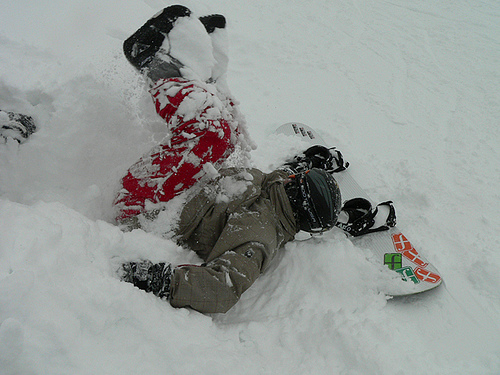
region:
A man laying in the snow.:
[88, 31, 419, 303]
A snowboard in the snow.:
[271, 126, 456, 325]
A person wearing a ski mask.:
[268, 160, 339, 238]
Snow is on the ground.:
[47, 241, 399, 371]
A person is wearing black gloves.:
[106, 245, 186, 302]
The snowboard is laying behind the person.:
[286, 128, 440, 310]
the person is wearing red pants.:
[144, 69, 235, 204]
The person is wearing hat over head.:
[300, 165, 341, 229]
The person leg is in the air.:
[118, 18, 245, 125]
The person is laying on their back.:
[71, 99, 351, 299]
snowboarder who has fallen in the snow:
[96, 0, 442, 320]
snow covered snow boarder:
[91, 4, 351, 314]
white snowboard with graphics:
[286, 113, 443, 308]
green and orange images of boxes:
[380, 230, 442, 295]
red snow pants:
[116, 68, 246, 233]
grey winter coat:
[162, 150, 297, 309]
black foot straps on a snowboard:
[298, 135, 402, 237]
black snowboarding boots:
[115, 2, 235, 64]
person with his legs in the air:
[110, 7, 340, 317]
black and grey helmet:
[288, 161, 343, 237]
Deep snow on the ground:
[2, 0, 499, 373]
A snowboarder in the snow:
[110, 3, 351, 323]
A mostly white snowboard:
[271, 118, 451, 326]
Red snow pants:
[109, 58, 229, 231]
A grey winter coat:
[165, 160, 306, 338]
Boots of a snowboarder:
[115, 3, 244, 76]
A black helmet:
[285, 169, 344, 239]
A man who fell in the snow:
[102, 5, 349, 325]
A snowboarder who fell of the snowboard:
[104, 10, 352, 332]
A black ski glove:
[110, 252, 172, 314]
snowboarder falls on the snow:
[98, 1, 379, 321]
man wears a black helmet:
[100, 0, 356, 321]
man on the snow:
[0, 0, 499, 356]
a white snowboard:
[260, 115, 445, 300]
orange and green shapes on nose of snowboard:
[361, 220, 446, 311]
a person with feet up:
[75, 0, 356, 325]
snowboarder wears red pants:
[110, 0, 350, 317]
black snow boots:
[113, 5, 240, 95]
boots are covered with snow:
[121, 7, 241, 94]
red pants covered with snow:
[118, 78, 255, 219]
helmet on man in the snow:
[280, 162, 340, 229]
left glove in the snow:
[120, 253, 176, 299]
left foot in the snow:
[123, 5, 183, 65]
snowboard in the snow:
[267, 117, 445, 294]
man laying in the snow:
[120, 18, 352, 322]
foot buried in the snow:
[5, 99, 34, 158]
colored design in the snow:
[378, 227, 440, 284]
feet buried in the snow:
[117, 3, 248, 72]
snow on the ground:
[23, 270, 122, 350]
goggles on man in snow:
[287, 167, 317, 227]